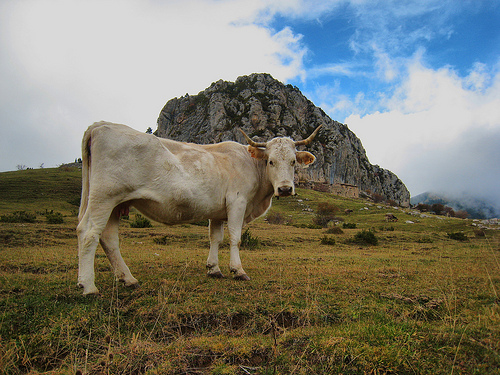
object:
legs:
[227, 198, 245, 266]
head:
[235, 122, 324, 196]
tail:
[81, 131, 92, 214]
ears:
[295, 149, 317, 166]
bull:
[77, 120, 324, 299]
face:
[265, 142, 297, 195]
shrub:
[346, 230, 378, 247]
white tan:
[161, 161, 176, 172]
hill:
[152, 72, 409, 208]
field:
[0, 168, 499, 373]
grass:
[0, 166, 499, 374]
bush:
[130, 213, 152, 228]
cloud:
[0, 0, 499, 219]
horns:
[294, 123, 322, 145]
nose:
[277, 185, 292, 194]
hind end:
[81, 120, 109, 168]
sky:
[0, 0, 499, 198]